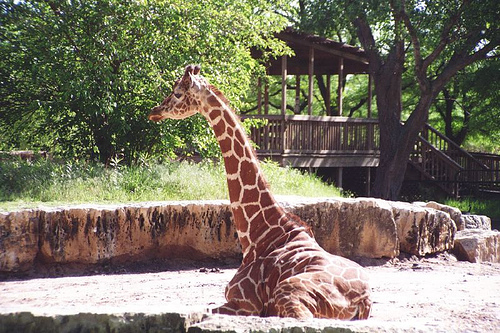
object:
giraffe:
[145, 67, 373, 320]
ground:
[134, 270, 500, 333]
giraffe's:
[143, 66, 375, 322]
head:
[137, 67, 224, 126]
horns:
[193, 65, 201, 76]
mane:
[210, 87, 231, 104]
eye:
[174, 93, 181, 98]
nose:
[148, 112, 156, 117]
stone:
[461, 214, 492, 229]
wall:
[4, 211, 135, 269]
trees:
[1, 3, 273, 176]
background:
[0, 2, 497, 201]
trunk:
[370, 122, 419, 202]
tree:
[320, 1, 492, 193]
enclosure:
[234, 28, 500, 207]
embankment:
[0, 310, 499, 330]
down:
[226, 299, 376, 319]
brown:
[247, 28, 499, 198]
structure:
[249, 25, 500, 199]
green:
[4, 146, 18, 156]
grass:
[27, 183, 50, 203]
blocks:
[456, 229, 499, 262]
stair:
[416, 160, 446, 168]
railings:
[420, 140, 431, 151]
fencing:
[462, 170, 496, 199]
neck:
[206, 109, 276, 216]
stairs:
[430, 172, 455, 182]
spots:
[227, 126, 235, 138]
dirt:
[5, 254, 493, 330]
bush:
[280, 173, 296, 188]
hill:
[4, 151, 321, 197]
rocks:
[395, 208, 456, 259]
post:
[280, 40, 289, 111]